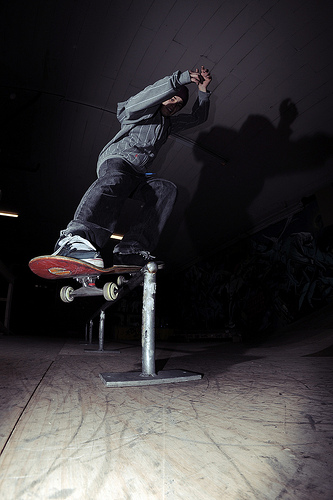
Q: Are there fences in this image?
A: No, there are no fences.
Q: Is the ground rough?
A: Yes, the ground is rough.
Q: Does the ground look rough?
A: Yes, the ground is rough.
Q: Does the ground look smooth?
A: No, the ground is rough.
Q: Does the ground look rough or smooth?
A: The ground is rough.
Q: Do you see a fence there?
A: No, there are no fences.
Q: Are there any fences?
A: No, there are no fences.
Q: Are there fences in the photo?
A: No, there are no fences.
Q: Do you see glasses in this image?
A: No, there are no glasses.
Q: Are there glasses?
A: No, there are no glasses.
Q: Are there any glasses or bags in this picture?
A: No, there are no glasses or bags.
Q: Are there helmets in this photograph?
A: No, there are no helmets.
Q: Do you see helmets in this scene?
A: No, there are no helmets.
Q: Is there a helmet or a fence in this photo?
A: No, there are no helmets or fences.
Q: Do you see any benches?
A: Yes, there is a bench.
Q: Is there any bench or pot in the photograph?
A: Yes, there is a bench.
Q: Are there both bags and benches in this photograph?
A: No, there is a bench but no bags.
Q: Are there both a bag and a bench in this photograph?
A: No, there is a bench but no bags.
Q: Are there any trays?
A: No, there are no trays.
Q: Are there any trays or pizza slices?
A: No, there are no trays or pizza slices.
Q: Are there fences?
A: No, there are no fences.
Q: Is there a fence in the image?
A: No, there are no fences.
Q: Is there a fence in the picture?
A: No, there are no fences.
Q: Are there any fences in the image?
A: No, there are no fences.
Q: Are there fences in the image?
A: No, there are no fences.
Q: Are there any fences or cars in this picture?
A: No, there are no fences or cars.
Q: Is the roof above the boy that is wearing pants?
A: Yes, the roof is above the boy.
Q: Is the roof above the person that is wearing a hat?
A: Yes, the roof is above the boy.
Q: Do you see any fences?
A: No, there are no fences.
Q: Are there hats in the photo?
A: Yes, there is a hat.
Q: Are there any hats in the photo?
A: Yes, there is a hat.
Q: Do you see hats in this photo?
A: Yes, there is a hat.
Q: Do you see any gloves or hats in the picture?
A: Yes, there is a hat.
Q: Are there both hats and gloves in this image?
A: No, there is a hat but no gloves.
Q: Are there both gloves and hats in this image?
A: No, there is a hat but no gloves.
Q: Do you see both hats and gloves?
A: No, there is a hat but no gloves.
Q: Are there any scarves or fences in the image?
A: No, there are no fences or scarves.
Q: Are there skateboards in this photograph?
A: Yes, there is a skateboard.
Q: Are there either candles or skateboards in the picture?
A: Yes, there is a skateboard.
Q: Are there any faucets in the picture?
A: No, there are no faucets.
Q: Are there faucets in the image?
A: No, there are no faucets.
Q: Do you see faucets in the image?
A: No, there are no faucets.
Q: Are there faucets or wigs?
A: No, there are no faucets or wigs.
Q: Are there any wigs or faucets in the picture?
A: No, there are no faucets or wigs.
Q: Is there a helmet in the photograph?
A: No, there are no helmets.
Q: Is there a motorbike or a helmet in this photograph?
A: No, there are no helmets or motorcycles.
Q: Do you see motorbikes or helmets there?
A: No, there are no helmets or motorbikes.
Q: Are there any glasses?
A: No, there are no glasses.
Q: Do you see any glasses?
A: No, there are no glasses.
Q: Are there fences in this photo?
A: No, there are no fences.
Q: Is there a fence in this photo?
A: No, there are no fences.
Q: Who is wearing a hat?
A: The boy is wearing a hat.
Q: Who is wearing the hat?
A: The boy is wearing a hat.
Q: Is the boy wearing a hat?
A: Yes, the boy is wearing a hat.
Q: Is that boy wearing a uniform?
A: No, the boy is wearing a hat.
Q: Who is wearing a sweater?
A: The boy is wearing a sweater.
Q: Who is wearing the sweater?
A: The boy is wearing a sweater.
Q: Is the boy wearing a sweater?
A: Yes, the boy is wearing a sweater.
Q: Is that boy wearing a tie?
A: No, the boy is wearing a sweater.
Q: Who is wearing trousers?
A: The boy is wearing trousers.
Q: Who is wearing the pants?
A: The boy is wearing trousers.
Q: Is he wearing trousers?
A: Yes, the boy is wearing trousers.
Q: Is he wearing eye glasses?
A: No, the boy is wearing trousers.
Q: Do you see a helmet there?
A: No, there are no helmets.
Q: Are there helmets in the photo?
A: No, there are no helmets.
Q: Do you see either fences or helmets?
A: No, there are no helmets or fences.